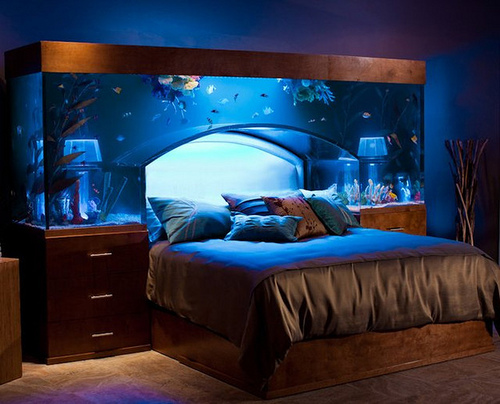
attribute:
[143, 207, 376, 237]
pillows — covered, different, plain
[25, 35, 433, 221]
aquarium — unique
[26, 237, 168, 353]
left drawers — brown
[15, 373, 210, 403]
floor — carpeted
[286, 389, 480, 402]
carpet — brown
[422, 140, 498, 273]
plant — bare, brown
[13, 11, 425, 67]
wall — blue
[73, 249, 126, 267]
handles — metal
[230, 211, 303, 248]
pillow — small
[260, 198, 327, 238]
pillow — square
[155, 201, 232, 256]
pillow — rectangular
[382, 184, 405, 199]
fish — striped, yellow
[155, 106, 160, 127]
fish — blue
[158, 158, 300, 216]
headboard — blue, cushioned